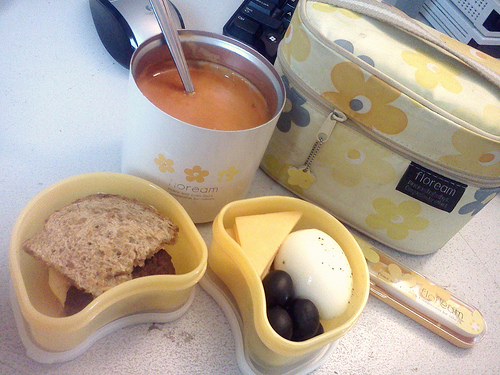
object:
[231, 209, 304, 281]
cheese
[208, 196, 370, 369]
container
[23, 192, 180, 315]
sandwich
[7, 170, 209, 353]
container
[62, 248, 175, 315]
meat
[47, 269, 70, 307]
egg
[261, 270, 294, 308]
olives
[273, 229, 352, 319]
boiled egg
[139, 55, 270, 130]
soup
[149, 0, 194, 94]
spoon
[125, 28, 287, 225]
thermos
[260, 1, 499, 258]
lunch box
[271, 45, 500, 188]
zipper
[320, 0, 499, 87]
handle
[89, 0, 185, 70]
mouse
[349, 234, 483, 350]
utensils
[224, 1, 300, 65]
keyboard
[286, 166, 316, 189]
charm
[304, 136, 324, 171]
chain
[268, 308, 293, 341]
food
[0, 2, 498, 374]
table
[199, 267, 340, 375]
lid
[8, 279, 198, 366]
lid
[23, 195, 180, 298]
bread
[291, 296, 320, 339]
food